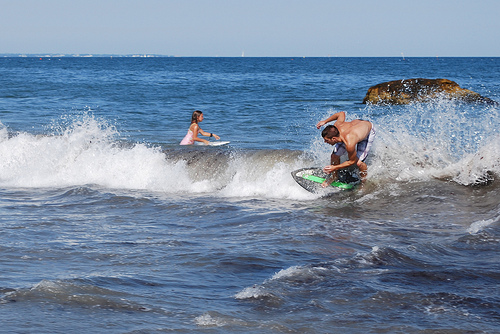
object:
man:
[315, 111, 376, 189]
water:
[0, 56, 500, 333]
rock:
[362, 78, 500, 108]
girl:
[179, 110, 220, 145]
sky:
[0, 0, 499, 59]